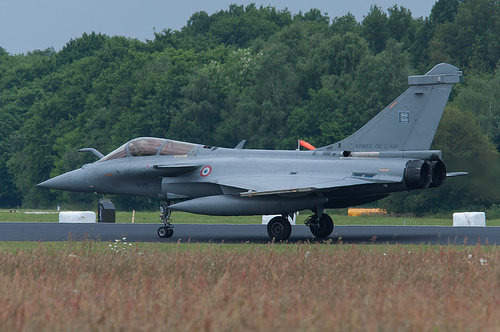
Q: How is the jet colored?
A: Grey.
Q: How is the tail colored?
A: Gray.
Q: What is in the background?
A: Trees.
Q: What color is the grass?
A: Brown.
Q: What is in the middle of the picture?
A: Jet.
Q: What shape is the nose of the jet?
A: Pointy.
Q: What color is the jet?
A: Grey.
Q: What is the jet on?
A: Runway.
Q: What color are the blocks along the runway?
A: White.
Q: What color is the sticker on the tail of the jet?
A: Green.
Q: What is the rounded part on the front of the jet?
A: Windshield.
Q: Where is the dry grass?
A: In front of the runway.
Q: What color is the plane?
A: Gray.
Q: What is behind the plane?
A: Trees.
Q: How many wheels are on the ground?
A: Three.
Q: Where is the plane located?
A: The runway.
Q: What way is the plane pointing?
A: Left.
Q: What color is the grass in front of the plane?
A: Brown.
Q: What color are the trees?
A: Green.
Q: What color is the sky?
A: Gray.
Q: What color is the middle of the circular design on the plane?
A: Blue.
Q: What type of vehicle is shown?
A: Jet.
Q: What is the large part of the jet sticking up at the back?
A: Tail.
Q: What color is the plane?
A: Gray.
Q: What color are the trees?
A: Green.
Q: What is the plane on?
A: Asphalt.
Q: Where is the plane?
A: On the asphalt.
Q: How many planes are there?
A: One.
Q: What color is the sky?
A: Blue.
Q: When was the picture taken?
A: Daytime.